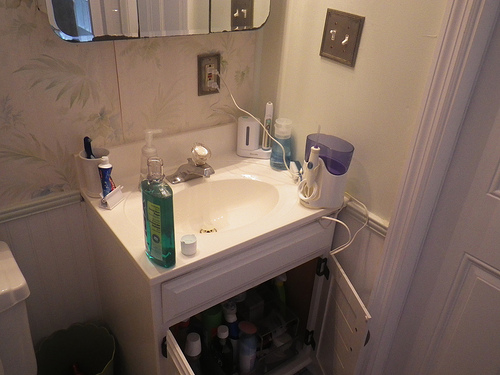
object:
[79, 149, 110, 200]
cup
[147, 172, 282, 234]
sink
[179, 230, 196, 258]
cap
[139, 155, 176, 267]
mouthwash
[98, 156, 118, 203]
toothpaste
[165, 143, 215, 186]
faucet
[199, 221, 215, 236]
drain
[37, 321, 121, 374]
garbage pail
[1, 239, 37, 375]
toilet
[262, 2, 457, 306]
wall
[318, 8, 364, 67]
light switch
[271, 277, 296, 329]
cleaner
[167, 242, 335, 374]
cabinet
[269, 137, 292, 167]
liquid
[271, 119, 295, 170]
bottle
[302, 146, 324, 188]
handle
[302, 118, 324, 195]
toothbrush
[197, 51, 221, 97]
outlet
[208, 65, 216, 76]
plugs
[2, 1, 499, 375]
bathroom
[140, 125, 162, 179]
soap dispenser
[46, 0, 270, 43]
mirror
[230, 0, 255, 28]
reflection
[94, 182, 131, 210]
stand